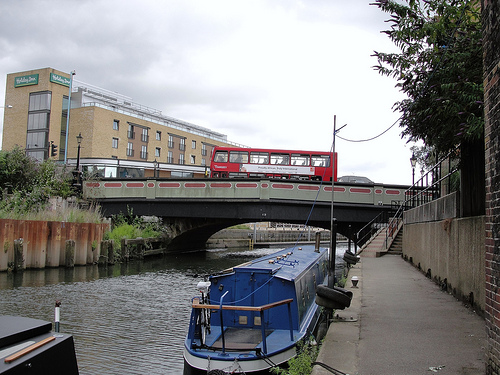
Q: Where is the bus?
A: On bridge.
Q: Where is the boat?
A: In water.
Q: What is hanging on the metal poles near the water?
A: Tires.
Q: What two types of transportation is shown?
A: Boat and bus.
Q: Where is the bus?
A: On bridge.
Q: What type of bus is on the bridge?
A: Double decker.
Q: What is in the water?
A: Boat.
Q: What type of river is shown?
A: Canal.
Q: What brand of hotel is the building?
A: Holiday Inn.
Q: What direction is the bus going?
A: Left.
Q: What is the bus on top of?
A: Bridge.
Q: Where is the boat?
A: On river.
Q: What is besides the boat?
A: Walkway.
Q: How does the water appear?
A: Ripply.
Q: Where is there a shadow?
A: Under bridge.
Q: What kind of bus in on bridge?
A: Double Decker.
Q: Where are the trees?
A: Side of river.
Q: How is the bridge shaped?
A: Arched.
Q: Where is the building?
A: Side of bridge.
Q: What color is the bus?
A: Red.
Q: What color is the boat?
A: Blue.